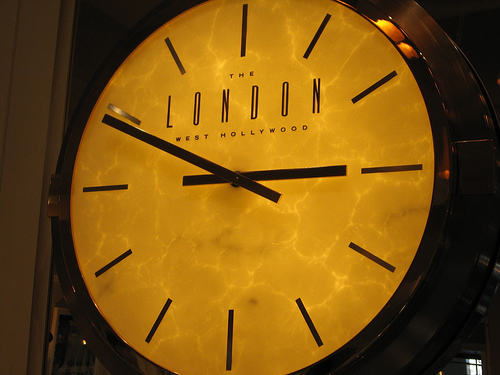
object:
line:
[295, 297, 325, 348]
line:
[225, 308, 233, 371]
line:
[347, 241, 397, 273]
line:
[348, 69, 399, 105]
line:
[239, 3, 249, 57]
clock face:
[66, 0, 436, 375]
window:
[465, 358, 482, 372]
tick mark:
[347, 240, 396, 275]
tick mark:
[358, 163, 422, 175]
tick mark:
[79, 184, 130, 195]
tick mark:
[300, 14, 335, 60]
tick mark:
[238, 3, 248, 59]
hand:
[100, 113, 282, 204]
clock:
[181, 164, 347, 187]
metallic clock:
[63, 1, 470, 373]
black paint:
[71, 27, 465, 209]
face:
[102, 22, 399, 327]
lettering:
[163, 76, 321, 130]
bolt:
[229, 172, 245, 188]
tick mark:
[359, 158, 424, 173]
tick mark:
[141, 298, 174, 344]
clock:
[70, 23, 436, 374]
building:
[0, 1, 499, 374]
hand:
[97, 114, 347, 204]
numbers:
[348, 69, 422, 273]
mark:
[294, 296, 324, 349]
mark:
[162, 37, 186, 76]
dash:
[223, 308, 235, 371]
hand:
[182, 165, 347, 186]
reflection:
[289, 12, 449, 350]